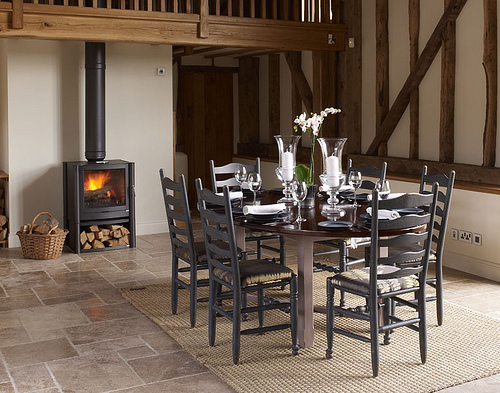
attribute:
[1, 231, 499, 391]
floor — tiled, ceramic tile, slippery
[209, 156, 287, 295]
chair — gray, dark brown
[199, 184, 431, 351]
table — set, brown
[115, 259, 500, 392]
rug — tan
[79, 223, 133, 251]
wood — chopped, piled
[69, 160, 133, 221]
fireplace — on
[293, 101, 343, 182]
flower — white, orchid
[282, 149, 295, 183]
candle — white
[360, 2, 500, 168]
wall panels — white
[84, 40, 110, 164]
stove pipe — black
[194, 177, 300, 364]
chair — wooden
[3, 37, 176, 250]
wall — white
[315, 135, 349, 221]
candleholder — glass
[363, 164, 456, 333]
chair — gray